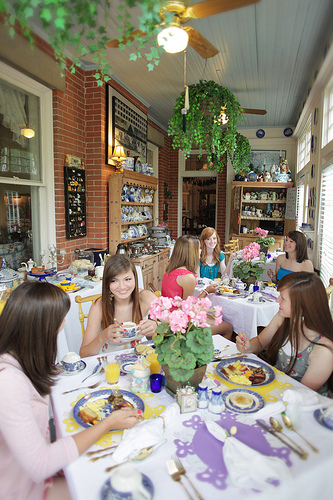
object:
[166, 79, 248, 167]
geranium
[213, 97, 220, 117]
pot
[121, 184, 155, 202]
dishes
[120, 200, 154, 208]
shelf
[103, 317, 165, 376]
lunch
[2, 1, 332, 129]
ceiling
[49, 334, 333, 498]
table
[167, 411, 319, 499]
silverware setting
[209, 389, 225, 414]
salt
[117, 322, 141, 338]
teacup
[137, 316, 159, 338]
ladies hand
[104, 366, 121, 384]
orange juice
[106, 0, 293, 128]
fans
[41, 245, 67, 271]
candleabra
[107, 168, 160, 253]
curio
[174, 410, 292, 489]
butterflies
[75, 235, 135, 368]
girls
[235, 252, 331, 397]
girl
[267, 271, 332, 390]
long brown hair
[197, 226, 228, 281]
girl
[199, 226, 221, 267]
red hair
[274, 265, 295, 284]
tube top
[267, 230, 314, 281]
girl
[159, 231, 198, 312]
girl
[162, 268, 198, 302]
red tanktop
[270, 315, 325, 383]
grey tanktop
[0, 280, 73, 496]
girl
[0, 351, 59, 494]
pink shirt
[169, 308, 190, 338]
flowers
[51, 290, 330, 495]
breakfast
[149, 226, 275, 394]
centerpieces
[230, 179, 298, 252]
breakfast buffet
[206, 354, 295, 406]
yellow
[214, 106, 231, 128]
light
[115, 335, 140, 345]
saucer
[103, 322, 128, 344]
girls hand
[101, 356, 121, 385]
glass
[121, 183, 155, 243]
display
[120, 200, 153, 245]
shelves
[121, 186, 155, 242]
dishes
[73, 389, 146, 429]
plate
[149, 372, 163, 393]
candle holder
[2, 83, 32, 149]
curtains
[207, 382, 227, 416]
shakers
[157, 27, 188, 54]
bright light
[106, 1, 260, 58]
fan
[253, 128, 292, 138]
plates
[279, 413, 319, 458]
spoons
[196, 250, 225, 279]
top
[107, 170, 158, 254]
cabinet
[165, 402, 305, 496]
place mats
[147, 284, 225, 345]
geraniums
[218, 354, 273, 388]
decorations